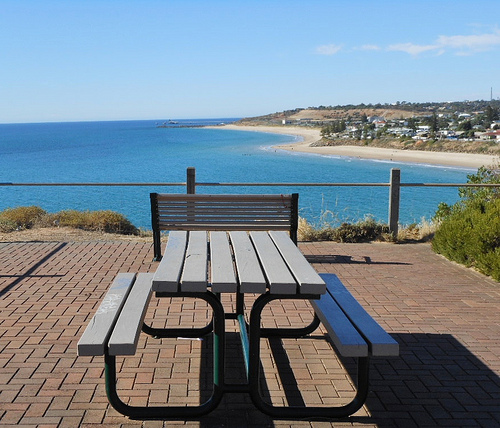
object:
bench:
[149, 192, 299, 262]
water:
[0, 117, 271, 186]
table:
[76, 229, 399, 423]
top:
[152, 230, 328, 300]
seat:
[78, 270, 153, 356]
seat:
[300, 274, 398, 357]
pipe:
[249, 294, 370, 420]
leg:
[151, 229, 165, 261]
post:
[186, 167, 196, 228]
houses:
[373, 117, 386, 123]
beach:
[300, 147, 496, 172]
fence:
[2, 165, 499, 235]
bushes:
[293, 208, 448, 242]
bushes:
[429, 164, 498, 289]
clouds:
[308, 20, 499, 67]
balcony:
[2, 230, 499, 425]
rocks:
[158, 125, 206, 128]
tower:
[491, 86, 493, 100]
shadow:
[301, 254, 414, 266]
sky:
[2, 2, 499, 122]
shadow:
[330, 307, 499, 427]